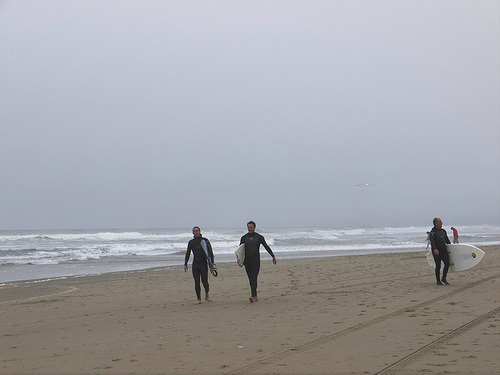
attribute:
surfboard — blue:
[193, 238, 221, 278]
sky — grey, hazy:
[1, 9, 465, 220]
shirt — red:
[443, 225, 463, 237]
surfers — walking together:
[155, 201, 285, 312]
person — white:
[423, 228, 433, 256]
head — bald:
[416, 223, 439, 238]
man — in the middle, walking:
[220, 217, 287, 303]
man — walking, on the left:
[173, 200, 220, 311]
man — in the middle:
[231, 214, 284, 316]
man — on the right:
[422, 212, 454, 286]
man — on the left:
[172, 221, 222, 305]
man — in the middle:
[232, 216, 285, 310]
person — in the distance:
[443, 222, 462, 246]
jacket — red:
[447, 227, 464, 243]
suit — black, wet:
[183, 235, 223, 302]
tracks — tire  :
[297, 279, 484, 357]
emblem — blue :
[455, 245, 477, 269]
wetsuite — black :
[239, 231, 272, 295]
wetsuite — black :
[238, 230, 268, 300]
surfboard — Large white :
[228, 242, 248, 268]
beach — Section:
[27, 244, 484, 362]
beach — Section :
[14, 241, 472, 344]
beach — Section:
[24, 250, 479, 373]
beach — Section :
[21, 240, 484, 370]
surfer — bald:
[426, 215, 456, 287]